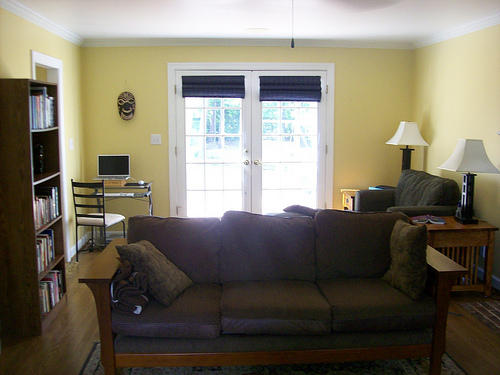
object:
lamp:
[436, 138, 500, 226]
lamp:
[384, 121, 429, 174]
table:
[341, 188, 361, 211]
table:
[409, 215, 497, 297]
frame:
[30, 49, 70, 262]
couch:
[76, 209, 471, 373]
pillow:
[381, 220, 428, 301]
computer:
[92, 154, 131, 180]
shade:
[182, 76, 245, 98]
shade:
[258, 75, 321, 102]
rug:
[80, 341, 466, 375]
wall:
[83, 46, 418, 232]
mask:
[117, 91, 136, 120]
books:
[55, 186, 59, 216]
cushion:
[77, 212, 126, 227]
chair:
[70, 178, 126, 262]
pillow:
[115, 239, 195, 307]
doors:
[250, 71, 327, 217]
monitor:
[97, 154, 131, 176]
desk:
[91, 180, 154, 237]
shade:
[385, 121, 430, 147]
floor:
[2, 235, 500, 373]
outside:
[183, 97, 319, 217]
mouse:
[137, 179, 144, 185]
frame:
[76, 237, 469, 373]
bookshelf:
[0, 78, 67, 339]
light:
[186, 98, 316, 219]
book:
[412, 215, 447, 224]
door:
[172, 67, 254, 220]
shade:
[436, 138, 500, 174]